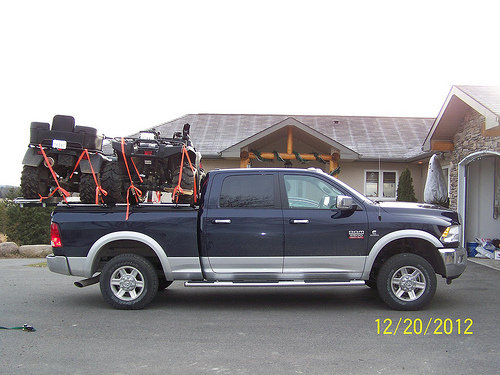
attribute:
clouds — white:
[1, 6, 488, 71]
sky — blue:
[0, 7, 500, 114]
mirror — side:
[337, 193, 355, 212]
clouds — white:
[182, 49, 233, 102]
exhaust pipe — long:
[71, 265, 106, 290]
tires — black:
[98, 251, 435, 309]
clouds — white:
[352, 42, 422, 82]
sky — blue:
[19, 43, 490, 129]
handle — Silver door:
[292, 217, 310, 224]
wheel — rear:
[97, 251, 160, 311]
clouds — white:
[2, 35, 50, 74]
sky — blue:
[183, 1, 317, 53]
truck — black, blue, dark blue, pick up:
[53, 160, 469, 318]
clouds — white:
[8, 2, 498, 195]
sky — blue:
[135, 12, 431, 97]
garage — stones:
[441, 122, 498, 268]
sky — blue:
[0, 0, 499, 83]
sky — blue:
[0, 8, 498, 186]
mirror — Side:
[340, 190, 361, 217]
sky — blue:
[0, 10, 484, 104]